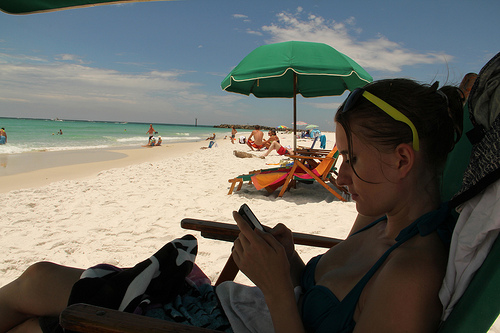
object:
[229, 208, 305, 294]
hands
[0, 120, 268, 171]
water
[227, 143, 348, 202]
chair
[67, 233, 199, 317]
towel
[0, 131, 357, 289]
beach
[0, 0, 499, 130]
sky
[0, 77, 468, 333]
girl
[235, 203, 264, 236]
cellphone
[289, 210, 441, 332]
bikini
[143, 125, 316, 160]
people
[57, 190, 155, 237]
wire fence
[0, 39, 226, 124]
clouds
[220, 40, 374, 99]
umbrella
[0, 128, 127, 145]
people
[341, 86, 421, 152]
sunglasses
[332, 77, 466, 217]
head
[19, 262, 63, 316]
knee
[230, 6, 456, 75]
clouds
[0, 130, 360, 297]
sand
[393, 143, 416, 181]
ear